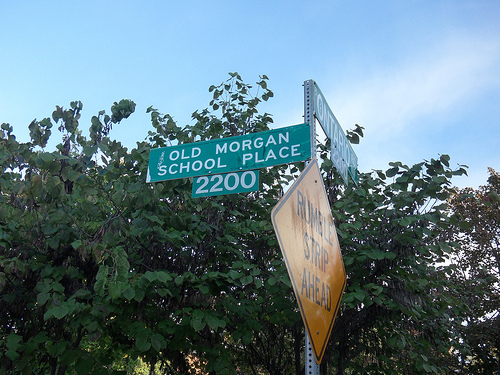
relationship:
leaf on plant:
[398, 188, 410, 199] [1, 70, 471, 371]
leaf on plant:
[397, 164, 429, 191] [13, 105, 483, 363]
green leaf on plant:
[438, 154, 457, 166] [356, 159, 461, 374]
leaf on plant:
[115, 97, 129, 111] [0, 98, 373, 325]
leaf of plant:
[180, 238, 230, 278] [41, 193, 303, 350]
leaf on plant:
[68, 176, 101, 202] [1, 70, 471, 371]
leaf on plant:
[126, 180, 146, 192] [1, 70, 471, 371]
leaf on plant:
[133, 187, 154, 209] [1, 70, 471, 371]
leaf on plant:
[151, 269, 172, 283] [1, 70, 471, 371]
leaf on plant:
[144, 268, 159, 283] [1, 70, 471, 371]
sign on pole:
[141, 121, 313, 182] [302, 78, 318, 373]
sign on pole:
[312, 83, 354, 183] [302, 78, 318, 373]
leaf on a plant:
[49, 303, 65, 318] [5, 110, 138, 347]